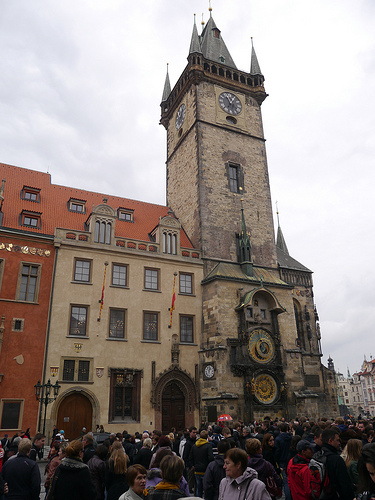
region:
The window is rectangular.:
[14, 257, 43, 310]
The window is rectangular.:
[70, 251, 98, 287]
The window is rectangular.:
[108, 258, 132, 292]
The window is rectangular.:
[137, 263, 161, 295]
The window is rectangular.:
[175, 268, 195, 299]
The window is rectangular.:
[173, 309, 197, 346]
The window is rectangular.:
[135, 303, 166, 348]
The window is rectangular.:
[104, 300, 132, 342]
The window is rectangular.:
[63, 296, 94, 345]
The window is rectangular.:
[53, 351, 95, 391]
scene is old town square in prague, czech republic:
[0, 0, 373, 499]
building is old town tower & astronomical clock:
[151, 0, 336, 420]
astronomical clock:
[246, 318, 276, 366]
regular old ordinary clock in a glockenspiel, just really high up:
[166, 86, 241, 133]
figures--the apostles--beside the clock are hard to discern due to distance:
[233, 320, 284, 399]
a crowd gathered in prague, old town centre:
[0, 398, 372, 494]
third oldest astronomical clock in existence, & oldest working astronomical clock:
[234, 315, 279, 361]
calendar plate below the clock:
[248, 370, 278, 406]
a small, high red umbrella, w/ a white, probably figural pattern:
[213, 410, 232, 424]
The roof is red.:
[0, 164, 188, 248]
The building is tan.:
[53, 229, 191, 429]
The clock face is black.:
[214, 82, 248, 123]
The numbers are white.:
[218, 88, 243, 109]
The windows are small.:
[45, 252, 200, 353]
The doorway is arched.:
[150, 358, 198, 443]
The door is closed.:
[143, 347, 200, 444]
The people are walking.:
[20, 414, 372, 495]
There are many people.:
[0, 413, 372, 494]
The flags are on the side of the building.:
[80, 262, 190, 322]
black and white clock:
[213, 92, 243, 122]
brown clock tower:
[161, 7, 291, 244]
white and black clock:
[165, 102, 199, 126]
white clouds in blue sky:
[20, 12, 55, 67]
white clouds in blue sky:
[33, 58, 65, 104]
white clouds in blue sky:
[61, 78, 87, 122]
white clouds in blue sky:
[102, 40, 123, 68]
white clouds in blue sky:
[298, 164, 362, 201]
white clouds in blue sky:
[290, 185, 331, 236]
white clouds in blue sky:
[344, 251, 372, 309]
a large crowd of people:
[11, 420, 366, 490]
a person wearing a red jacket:
[286, 436, 319, 494]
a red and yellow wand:
[100, 257, 120, 315]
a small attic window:
[116, 202, 134, 224]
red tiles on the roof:
[41, 183, 67, 216]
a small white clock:
[198, 355, 229, 381]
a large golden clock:
[248, 362, 278, 404]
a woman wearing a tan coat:
[217, 450, 264, 499]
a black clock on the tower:
[212, 81, 250, 121]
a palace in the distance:
[336, 367, 373, 415]